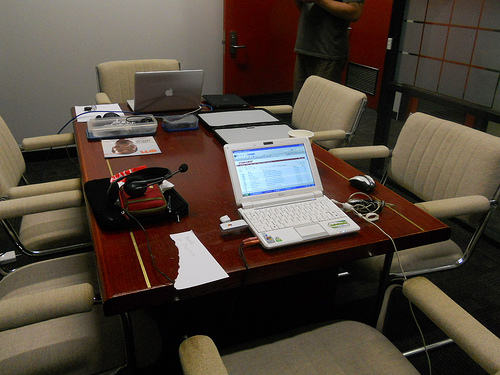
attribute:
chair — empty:
[353, 109, 498, 267]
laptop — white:
[218, 140, 361, 261]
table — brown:
[189, 180, 228, 237]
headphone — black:
[113, 160, 196, 207]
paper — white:
[162, 225, 236, 305]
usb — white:
[215, 219, 247, 237]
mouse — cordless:
[343, 169, 381, 196]